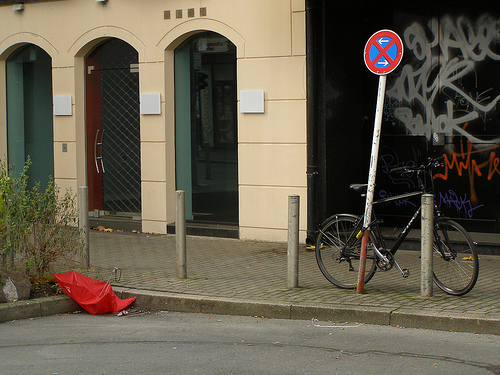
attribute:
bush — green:
[0, 154, 93, 296]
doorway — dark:
[161, 29, 249, 234]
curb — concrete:
[142, 273, 432, 335]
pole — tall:
[349, 27, 406, 295]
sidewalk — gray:
[45, 221, 498, 320]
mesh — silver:
[104, 36, 140, 210]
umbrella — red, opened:
[28, 233, 193, 373]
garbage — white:
[2, 242, 129, 330]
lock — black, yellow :
[352, 218, 377, 243]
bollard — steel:
[174, 188, 189, 280]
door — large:
[61, 34, 173, 269]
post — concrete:
[289, 185, 303, 300]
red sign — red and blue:
[305, 24, 416, 79]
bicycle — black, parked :
[313, 152, 481, 296]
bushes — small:
[4, 154, 93, 304]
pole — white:
[353, 74, 387, 292]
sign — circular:
[357, 23, 408, 80]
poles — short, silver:
[154, 197, 330, 294]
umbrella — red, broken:
[51, 263, 137, 313]